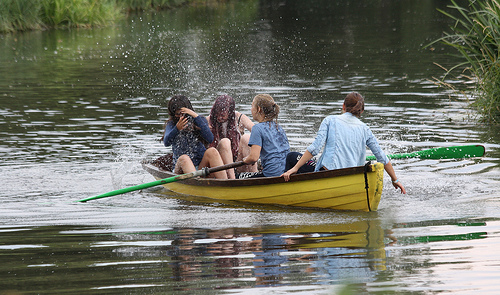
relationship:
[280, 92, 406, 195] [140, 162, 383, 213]
friend riding in base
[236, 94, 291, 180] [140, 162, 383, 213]
friend riding in base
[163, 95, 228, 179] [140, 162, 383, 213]
female riding in base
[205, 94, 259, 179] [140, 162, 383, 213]
friend riding in base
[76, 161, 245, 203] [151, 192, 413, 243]
oar hanging over water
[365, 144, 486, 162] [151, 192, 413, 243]
oar hanging over water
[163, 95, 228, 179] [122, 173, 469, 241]
female shielding herself from water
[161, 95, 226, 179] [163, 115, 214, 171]
female wearing blue top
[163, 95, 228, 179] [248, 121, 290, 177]
female wearing gray shirt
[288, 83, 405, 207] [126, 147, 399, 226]
friend playing in boat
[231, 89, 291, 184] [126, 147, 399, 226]
friend playing in boat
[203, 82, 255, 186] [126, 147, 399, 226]
friend playing in boat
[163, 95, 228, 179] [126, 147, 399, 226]
female playing in boat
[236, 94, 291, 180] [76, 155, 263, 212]
friend holding oar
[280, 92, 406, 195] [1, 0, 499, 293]
friend holding hand in water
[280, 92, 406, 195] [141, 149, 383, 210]
friend sitting in boat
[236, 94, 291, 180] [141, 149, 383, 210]
friend sitting in boat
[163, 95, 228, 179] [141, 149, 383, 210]
female sitting in boat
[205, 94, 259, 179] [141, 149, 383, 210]
friend sitting in boat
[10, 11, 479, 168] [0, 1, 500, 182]
water spray in air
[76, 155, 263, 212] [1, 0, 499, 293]
oar in water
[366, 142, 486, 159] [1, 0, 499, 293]
oar out of water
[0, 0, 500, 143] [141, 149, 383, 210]
grass in front of boat